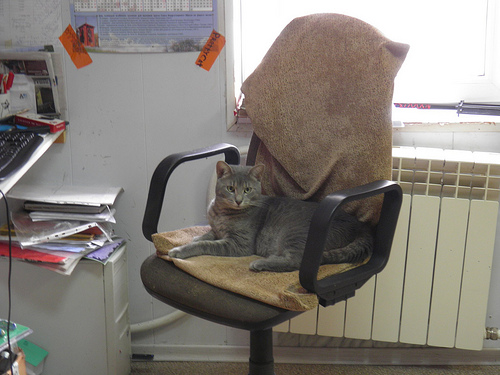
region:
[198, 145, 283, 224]
head of a cat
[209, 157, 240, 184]
ear of a cat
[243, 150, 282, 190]
ear of a cat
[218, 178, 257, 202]
eye of a cat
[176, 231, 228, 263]
leg of a cat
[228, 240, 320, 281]
leg of a cat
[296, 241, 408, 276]
tail of a cat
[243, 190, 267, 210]
whisker of a cat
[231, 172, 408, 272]
body of a cat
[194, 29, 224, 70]
orange tape on wall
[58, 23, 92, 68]
orange tape on wall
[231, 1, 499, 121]
light coming through window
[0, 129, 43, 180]
black keyboard on white desk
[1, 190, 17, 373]
black cable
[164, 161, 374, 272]
grey cat sitting in a chair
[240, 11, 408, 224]
brown towel on back of chair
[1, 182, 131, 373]
stack of papers on computer tower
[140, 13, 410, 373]
grey cat sitting in desk chair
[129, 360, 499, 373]
carpeted floor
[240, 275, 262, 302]
edge of a cloth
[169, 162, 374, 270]
A grey cat with pointy ears.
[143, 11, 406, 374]
A grey and black desk chair.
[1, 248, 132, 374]
A tall white cpu unit on the floor.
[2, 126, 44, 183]
A black keyboard.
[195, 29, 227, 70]
Orange piece of tape with black writing on it.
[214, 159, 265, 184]
Pointy grey ears of a cat.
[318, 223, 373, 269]
A grey cat's tail.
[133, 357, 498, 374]
Brown carpeted floor.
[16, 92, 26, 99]
A black A on a paper by the keyboard.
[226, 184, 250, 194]
Two eyes of a cat.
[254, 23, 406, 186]
brown towel on a chair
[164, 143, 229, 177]
black arm rest of chair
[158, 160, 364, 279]
cat laying on chair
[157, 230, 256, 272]
front paws of a cat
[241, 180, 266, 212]
white whiskers on cat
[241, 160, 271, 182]
grey and orange ears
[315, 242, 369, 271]
black and white tail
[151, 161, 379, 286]
grey cat on a chair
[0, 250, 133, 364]
computer case on floor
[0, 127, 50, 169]
black key board on desk